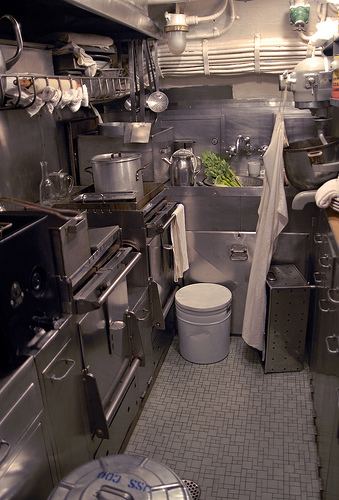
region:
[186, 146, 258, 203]
green leaves in sink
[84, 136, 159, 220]
silver pot on table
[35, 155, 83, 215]
glass bottle on table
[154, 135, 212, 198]
silver jug on table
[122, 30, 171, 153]
utensils hanging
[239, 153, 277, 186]
cup on sink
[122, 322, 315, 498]
the grey tiled floor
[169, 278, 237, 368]
a white pail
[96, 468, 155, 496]
blue writing on the top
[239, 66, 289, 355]
apron on the mixer nozzle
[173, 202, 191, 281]
towel on the handle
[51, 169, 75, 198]
a pitcher on the counter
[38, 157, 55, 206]
a vase on the other side of vase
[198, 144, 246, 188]
vegetables in sink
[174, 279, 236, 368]
cylindrical white container on floor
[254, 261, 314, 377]
silver metal box with holes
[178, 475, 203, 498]
silver drain in floor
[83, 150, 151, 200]
large silver pot on stove top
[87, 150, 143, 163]
large silver pot lid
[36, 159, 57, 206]
long neck glass container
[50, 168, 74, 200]
clear glass serving pitcher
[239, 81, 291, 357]
long white kitchen apron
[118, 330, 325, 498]
gray squared pattern linoleum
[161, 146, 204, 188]
silver metal serving pitcher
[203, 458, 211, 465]
a white tile on a floor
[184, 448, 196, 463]
a white tile on a floor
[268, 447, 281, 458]
a white tile on a floor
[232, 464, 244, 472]
a white tile on a floor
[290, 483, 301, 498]
a white tile on a floor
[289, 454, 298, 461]
a white tile on a floor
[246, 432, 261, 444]
a white tile on a floor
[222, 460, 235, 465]
a white tile on a floor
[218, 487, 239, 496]
a white tile on a floor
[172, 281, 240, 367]
white bucket with lid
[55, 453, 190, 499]
silver trashcan with lid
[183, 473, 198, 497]
drain in the floor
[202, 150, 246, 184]
vegetables in the sink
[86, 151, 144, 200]
large pot on the stovetop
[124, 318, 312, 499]
patterned flooring in the kitchen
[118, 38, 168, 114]
pots hanging from the wall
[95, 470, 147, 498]
blue writing on trashcan lid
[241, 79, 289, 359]
white apron hanging in the kitchen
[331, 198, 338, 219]
stack of plates on the counter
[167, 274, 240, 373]
a white cylindrical container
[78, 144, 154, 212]
the pot is color silver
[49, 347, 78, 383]
handle on a counter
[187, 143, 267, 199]
celery in a sink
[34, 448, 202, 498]
lid of a can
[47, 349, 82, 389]
handl on the cabinet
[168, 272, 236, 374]
the container is round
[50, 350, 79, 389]
the handle of a cabinet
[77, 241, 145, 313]
handle of a stove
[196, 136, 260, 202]
green vegetables in a sink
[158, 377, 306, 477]
the floor is gray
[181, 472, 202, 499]
a drain on the floor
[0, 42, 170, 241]
a rack above the stove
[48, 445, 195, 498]
a trash can of metal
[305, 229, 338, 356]
metal handles of cabinets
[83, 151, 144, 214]
covered pot sitting on stove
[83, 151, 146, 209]
covered pot sitting on oven